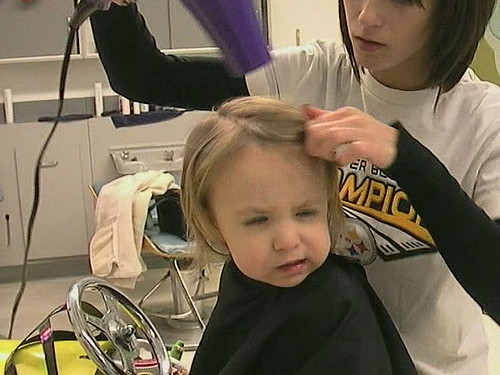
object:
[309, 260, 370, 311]
shoulder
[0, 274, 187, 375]
car chair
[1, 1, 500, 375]
hair salon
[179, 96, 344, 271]
hair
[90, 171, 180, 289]
smock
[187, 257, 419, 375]
cape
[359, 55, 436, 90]
neck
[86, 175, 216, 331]
chair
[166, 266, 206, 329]
legs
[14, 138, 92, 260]
door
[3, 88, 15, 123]
bottle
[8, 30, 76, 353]
cord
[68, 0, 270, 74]
blow dryer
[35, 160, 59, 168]
handle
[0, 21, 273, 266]
cabinet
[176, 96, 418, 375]
child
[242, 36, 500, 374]
shirt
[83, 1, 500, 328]
shirt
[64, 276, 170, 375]
wheel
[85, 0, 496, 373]
girl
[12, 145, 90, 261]
drawer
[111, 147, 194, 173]
sink